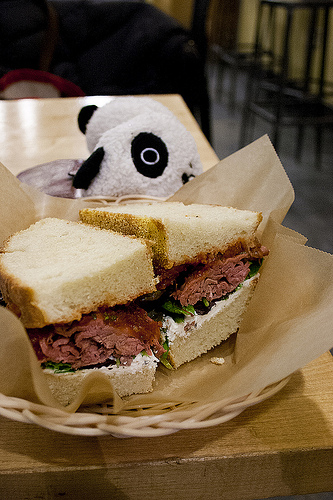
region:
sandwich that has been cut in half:
[3, 200, 295, 413]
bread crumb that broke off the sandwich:
[209, 353, 227, 365]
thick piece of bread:
[4, 223, 158, 327]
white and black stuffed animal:
[58, 91, 218, 203]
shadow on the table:
[244, 388, 332, 492]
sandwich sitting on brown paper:
[2, 165, 324, 407]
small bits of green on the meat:
[102, 313, 118, 325]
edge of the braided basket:
[2, 389, 306, 438]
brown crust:
[0, 271, 47, 329]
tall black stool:
[238, 5, 314, 162]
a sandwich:
[48, 234, 173, 417]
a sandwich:
[71, 288, 224, 496]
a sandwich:
[116, 330, 188, 436]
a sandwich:
[70, 304, 167, 448]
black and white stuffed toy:
[60, 112, 198, 199]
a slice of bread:
[76, 196, 266, 273]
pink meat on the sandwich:
[35, 302, 167, 373]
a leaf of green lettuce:
[161, 296, 212, 322]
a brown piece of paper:
[0, 132, 332, 418]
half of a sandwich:
[0, 210, 166, 419]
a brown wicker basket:
[0, 192, 299, 444]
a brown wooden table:
[0, 93, 332, 499]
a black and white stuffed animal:
[66, 95, 205, 200]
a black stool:
[233, 0, 331, 172]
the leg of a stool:
[267, 7, 295, 154]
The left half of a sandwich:
[0, 221, 156, 393]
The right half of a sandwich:
[118, 189, 268, 347]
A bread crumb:
[207, 353, 225, 368]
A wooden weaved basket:
[0, 393, 231, 438]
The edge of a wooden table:
[6, 440, 290, 497]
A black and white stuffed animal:
[68, 97, 201, 195]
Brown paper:
[207, 145, 329, 392]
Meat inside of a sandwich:
[44, 310, 157, 361]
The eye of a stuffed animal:
[127, 130, 174, 174]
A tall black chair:
[247, 1, 325, 158]